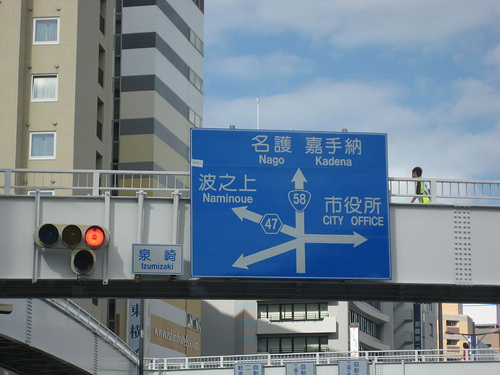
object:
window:
[32, 17, 60, 47]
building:
[0, 1, 207, 357]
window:
[32, 73, 59, 101]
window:
[29, 130, 57, 158]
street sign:
[192, 128, 391, 281]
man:
[407, 167, 433, 205]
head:
[410, 167, 424, 177]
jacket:
[417, 183, 432, 205]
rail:
[1, 165, 499, 206]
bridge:
[0, 166, 499, 304]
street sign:
[131, 243, 185, 279]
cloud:
[197, 0, 499, 205]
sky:
[203, 2, 499, 205]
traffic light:
[35, 224, 108, 274]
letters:
[257, 152, 286, 168]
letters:
[313, 155, 353, 167]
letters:
[201, 192, 255, 205]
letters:
[323, 214, 342, 227]